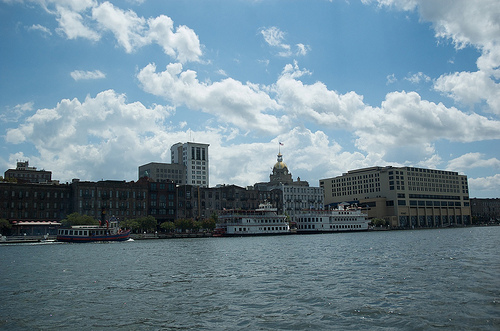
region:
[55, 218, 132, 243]
a white and red boat on the water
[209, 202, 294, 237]
a large white boat on the water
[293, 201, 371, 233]
a large white boat on the water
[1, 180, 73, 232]
a brown building near the water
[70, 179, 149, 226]
a brown building near the water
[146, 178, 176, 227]
a brown building near the water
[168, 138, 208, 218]
a white building near the water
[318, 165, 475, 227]
a large beige building near the water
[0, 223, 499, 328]
a large body of water near some buildings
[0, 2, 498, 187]
a sky with white clouds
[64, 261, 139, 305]
the water is calm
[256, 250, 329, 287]
the water is calm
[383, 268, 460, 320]
the water is calm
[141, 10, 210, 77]
this is a cloud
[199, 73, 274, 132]
this is a cloud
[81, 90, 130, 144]
this is a cloud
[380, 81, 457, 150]
this is a cloud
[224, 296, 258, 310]
ripple in the water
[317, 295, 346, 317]
ripple in the water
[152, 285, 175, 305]
ripple in the water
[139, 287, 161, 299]
ripple in the water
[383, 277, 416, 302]
ripple in the water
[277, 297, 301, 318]
ripple in the water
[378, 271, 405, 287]
ripple in the water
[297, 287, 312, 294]
ripple in the water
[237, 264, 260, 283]
ripple in the water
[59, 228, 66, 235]
window on a boat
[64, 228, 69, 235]
window on a boat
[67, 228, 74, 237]
window on a boat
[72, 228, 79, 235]
window on a boat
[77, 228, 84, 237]
window on a boat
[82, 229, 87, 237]
window on a boat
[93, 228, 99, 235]
window on a boat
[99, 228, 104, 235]
window on a boat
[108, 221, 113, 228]
window on a boat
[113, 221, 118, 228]
window on a boat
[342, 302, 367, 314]
wave in the water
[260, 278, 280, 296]
wave in the water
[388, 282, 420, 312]
wave in the water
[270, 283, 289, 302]
wave in the water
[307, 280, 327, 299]
wave in the water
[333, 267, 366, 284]
wave in the water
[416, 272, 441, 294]
wave in the water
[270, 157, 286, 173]
dome on the top of building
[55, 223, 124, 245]
red white and blue boat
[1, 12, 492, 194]
The cloudy sky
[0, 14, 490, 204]
A cloudy sky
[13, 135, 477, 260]
The buildings in the background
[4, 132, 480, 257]
A set of buildings in the background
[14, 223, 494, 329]
The body of water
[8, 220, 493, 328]
A body of water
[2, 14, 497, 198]
the cloudy sky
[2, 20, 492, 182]
A cloudy sky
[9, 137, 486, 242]
The buildings in the background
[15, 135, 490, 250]
A set of buildings in the background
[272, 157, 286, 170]
the dome is gold